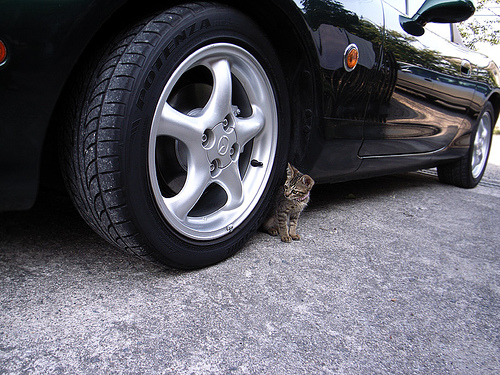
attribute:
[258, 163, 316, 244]
kitten — striped, brown, looking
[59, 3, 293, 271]
tire — black, new, clean, driver's side, on back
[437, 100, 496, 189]
tire — black, new, clean, driver's side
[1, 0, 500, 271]
car — black, reflection, reflecting, 2 door, reflective, shiny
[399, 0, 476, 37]
mirror — on side, on driver's side, driver side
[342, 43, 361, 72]
reflector — round, orange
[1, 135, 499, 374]
ground — gravel, grey, smooth, asphalt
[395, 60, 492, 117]
car — silver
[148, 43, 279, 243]
wheel — on front, chrome, clean, silver, round, covered, aluminum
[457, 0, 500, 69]
sky — cloudy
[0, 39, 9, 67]
light — turn signal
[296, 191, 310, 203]
collar — red